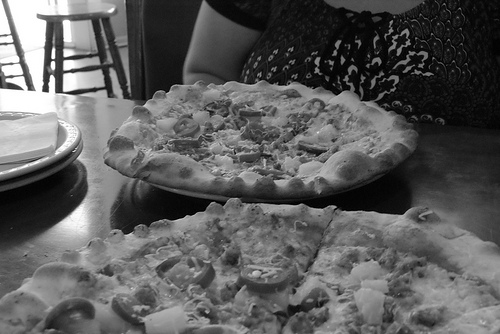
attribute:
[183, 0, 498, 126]
lady — light skinned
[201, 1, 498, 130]
blouse — floral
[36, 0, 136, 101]
chair — wooden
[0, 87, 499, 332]
table — wooden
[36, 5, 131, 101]
stool — wood